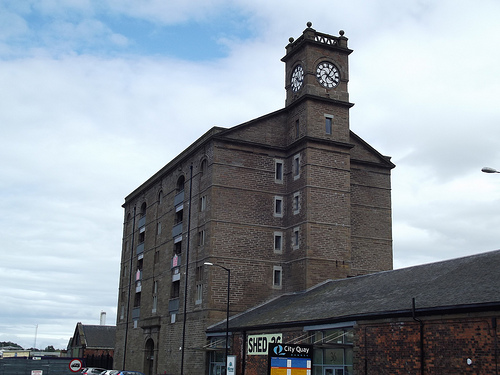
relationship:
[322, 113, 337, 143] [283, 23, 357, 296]
window on tower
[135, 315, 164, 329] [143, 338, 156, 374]
overhang above door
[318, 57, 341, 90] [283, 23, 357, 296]
clock on tower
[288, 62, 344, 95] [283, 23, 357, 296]
clocks are on tower